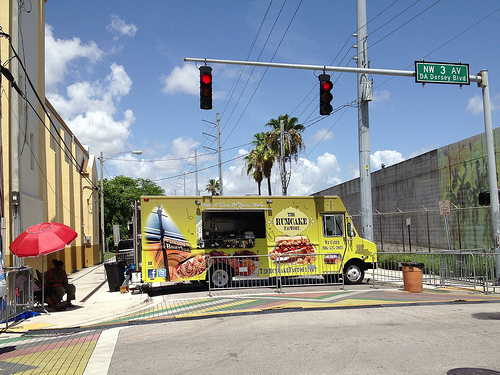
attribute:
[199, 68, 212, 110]
signal — black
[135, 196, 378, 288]
truck — foodtruck, large, yellow, decorated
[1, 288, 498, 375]
road — pavement, grey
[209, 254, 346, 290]
guardrail — metal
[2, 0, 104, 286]
building — large, beige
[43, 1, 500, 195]
sky — blue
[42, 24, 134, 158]
clouds — white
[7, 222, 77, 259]
umbrella — red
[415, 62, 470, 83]
sign — green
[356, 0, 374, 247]
pole — grey